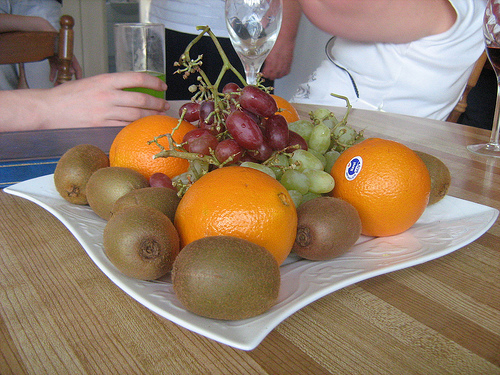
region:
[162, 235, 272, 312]
kiwi fruit in the front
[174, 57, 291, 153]
some red grapes missing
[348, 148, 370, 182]
tag on the orange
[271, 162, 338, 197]
green grapes between oranges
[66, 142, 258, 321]
five kiwi fruits on the plate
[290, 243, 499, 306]
plate the fruit is on is white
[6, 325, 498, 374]
plate is on the wood table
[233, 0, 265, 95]
empty glass by the fruit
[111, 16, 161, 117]
hand holding liquid in glass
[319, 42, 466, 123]
person with white shirt on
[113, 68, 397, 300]
A PLATE FULL OF FRUITS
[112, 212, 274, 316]
the pears are green in color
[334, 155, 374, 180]
the price tag is white in color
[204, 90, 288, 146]
the grapes are rippen maroon in color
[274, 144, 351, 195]
the grapes are green in color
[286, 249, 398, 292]
the plate is white in color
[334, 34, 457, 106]
the blouse is white in color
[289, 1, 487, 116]
side of white shirt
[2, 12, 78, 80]
arm on back of chair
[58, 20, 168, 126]
hand on drinking glass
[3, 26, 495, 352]
fruit on white plate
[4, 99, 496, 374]
surface of wood table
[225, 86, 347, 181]
two colored grapes on stems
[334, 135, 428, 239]
dimpled skin on orange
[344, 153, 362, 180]
label on orange skin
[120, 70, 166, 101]
green liquid in glass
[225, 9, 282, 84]
empty glass with stem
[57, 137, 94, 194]
THIS IS A KIWI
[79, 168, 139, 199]
THIS IS A KIWI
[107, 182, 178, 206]
THIS IS A KIWI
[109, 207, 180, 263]
THIS IS A KIWI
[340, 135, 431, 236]
THIS IS AN ORANGE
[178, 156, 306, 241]
THIS IS AN ORANGE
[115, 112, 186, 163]
THIS IS AN ORANGE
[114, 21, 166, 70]
THIS IS A GLASS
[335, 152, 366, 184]
the sticker on the orange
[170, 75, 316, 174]
the red grape bunch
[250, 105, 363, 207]
the green grape bunch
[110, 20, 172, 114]
the glass with green liquid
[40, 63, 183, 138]
the hand holding the glass with green liquid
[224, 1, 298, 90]
the empty wine glass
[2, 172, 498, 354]
the white ceramic plate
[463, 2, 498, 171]
the wine glass with red wine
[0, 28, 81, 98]
the back of the chair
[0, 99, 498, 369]
the table with fruit